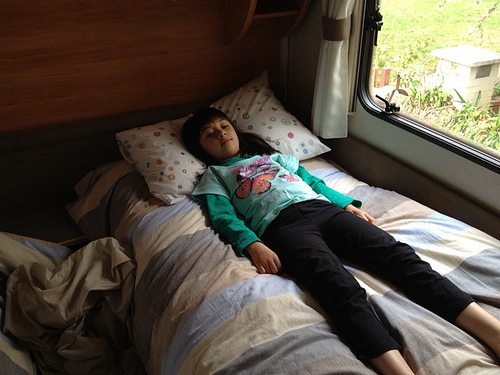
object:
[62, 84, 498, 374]
bed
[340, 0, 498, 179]
window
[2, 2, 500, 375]
trailer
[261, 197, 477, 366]
pants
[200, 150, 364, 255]
shirt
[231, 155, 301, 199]
butterflies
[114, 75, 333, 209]
pillow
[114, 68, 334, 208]
case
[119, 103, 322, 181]
spots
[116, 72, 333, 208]
pillowcase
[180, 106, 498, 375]
girl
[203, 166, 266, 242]
arm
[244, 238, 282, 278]
hand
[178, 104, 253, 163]
head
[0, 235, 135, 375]
sheet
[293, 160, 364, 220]
sleeve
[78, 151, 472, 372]
spread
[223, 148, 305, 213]
design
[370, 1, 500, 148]
plants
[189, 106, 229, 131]
bangs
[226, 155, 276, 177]
writing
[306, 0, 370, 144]
curtains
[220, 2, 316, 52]
shelf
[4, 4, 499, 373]
camper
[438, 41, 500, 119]
wall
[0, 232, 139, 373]
blankets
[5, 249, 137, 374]
floor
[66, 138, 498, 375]
bedspread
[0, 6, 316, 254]
wall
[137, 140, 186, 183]
dots